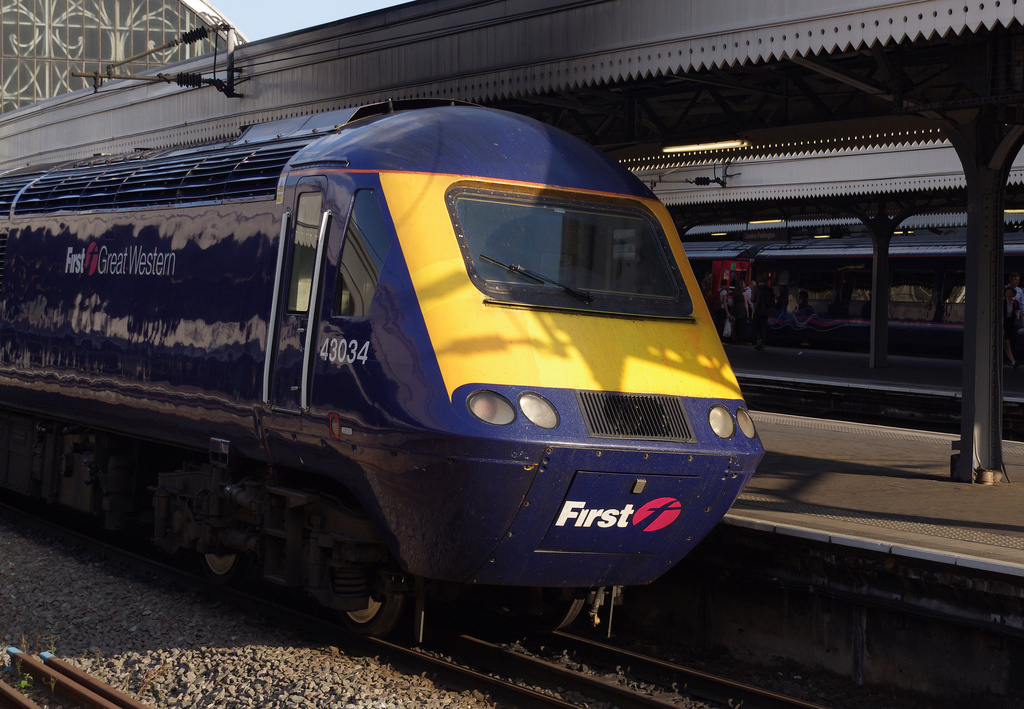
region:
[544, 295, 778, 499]
A person eating a orange.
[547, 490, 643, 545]
The word First on the front of the train.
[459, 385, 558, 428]
The front left headlights of the train.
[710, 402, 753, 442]
The front right headlights of the train.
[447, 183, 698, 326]
The front window of the train.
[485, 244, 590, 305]
The windshield wiper on the window.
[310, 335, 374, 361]
The numbers on the side of the train.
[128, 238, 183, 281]
The word Western on the side of the train.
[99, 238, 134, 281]
The word Great on the side of the train.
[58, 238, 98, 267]
The word First on the side of the train.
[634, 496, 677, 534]
The red emblem next to the word First on the front of the train.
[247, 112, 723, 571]
the train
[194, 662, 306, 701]
small rocks o the tracks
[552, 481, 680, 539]
a logo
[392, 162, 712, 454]
the train is yellow and blue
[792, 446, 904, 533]
the sidewalk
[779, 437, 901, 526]
a shadow on the sidewalk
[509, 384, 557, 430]
a headlight on the train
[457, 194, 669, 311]
a window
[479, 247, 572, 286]
a windshield wiper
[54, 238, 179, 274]
writing on the train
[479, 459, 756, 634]
First written on the front of train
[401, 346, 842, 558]
Lights on the front of the passenger train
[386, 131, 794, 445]
Windhield on the front of the train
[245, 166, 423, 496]
Metal railing on the side of the train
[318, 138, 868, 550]
Yellow paint on the front of the passenger train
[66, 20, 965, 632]
Passenger tra8n stopped at the station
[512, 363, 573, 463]
a light on the train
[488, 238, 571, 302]
a wiper on the train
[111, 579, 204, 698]
gravel between the tracks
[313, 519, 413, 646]
a wheel on the train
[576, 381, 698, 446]
a vent on the train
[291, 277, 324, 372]
handles on the side of the train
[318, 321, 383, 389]
numbers on the train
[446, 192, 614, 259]
a window in the train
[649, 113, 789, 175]
a light on the building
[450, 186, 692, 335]
frontal window of the train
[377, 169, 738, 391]
frontal frame yellow of the train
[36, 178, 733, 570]
blue firts wagon of the train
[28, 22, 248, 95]
electric pole on the wall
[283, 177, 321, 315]
right window of the train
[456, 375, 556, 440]
left side light of the train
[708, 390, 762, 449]
right side light of the train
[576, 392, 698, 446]
black frontal grating of the train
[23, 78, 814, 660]
Blue and yellow train.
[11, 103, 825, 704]
Train on railroad tracks.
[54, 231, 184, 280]
Train line logo.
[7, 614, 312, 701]
Gravel between railroad tracks.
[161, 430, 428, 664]
Metal wheels on railroad tracks.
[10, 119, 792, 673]
navy blue and yellow train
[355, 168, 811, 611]
yellow train cockpit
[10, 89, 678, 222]
navy blue train roof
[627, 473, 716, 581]
red symbol on front of train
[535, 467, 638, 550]
white words on front of train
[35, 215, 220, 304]
white words on train side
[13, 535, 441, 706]
brown gravel next to train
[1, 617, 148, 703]
rusty brown train tracks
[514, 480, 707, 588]
red and white logo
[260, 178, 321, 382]
grey bars on door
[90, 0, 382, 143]
blue and white sky